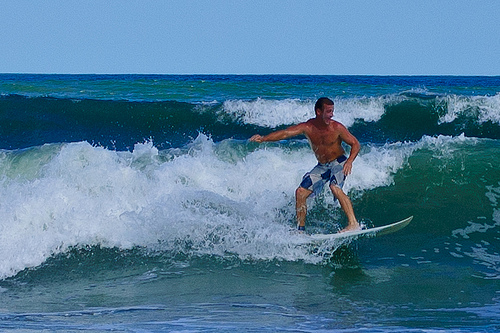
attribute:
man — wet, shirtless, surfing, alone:
[248, 98, 363, 235]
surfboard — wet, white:
[312, 215, 414, 241]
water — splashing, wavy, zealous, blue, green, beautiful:
[0, 72, 500, 333]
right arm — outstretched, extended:
[249, 122, 309, 144]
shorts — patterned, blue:
[299, 153, 352, 193]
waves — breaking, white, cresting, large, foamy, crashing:
[0, 85, 500, 285]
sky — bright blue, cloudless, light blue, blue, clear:
[0, 1, 500, 78]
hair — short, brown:
[315, 97, 333, 111]